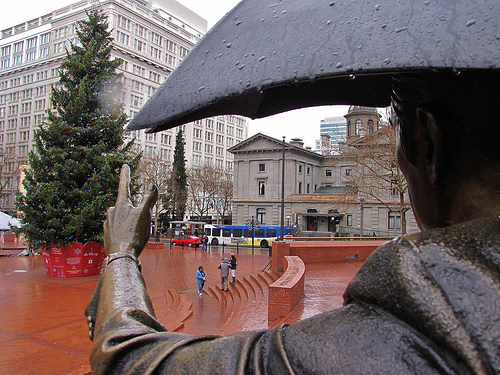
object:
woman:
[195, 265, 206, 297]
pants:
[197, 283, 205, 293]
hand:
[100, 162, 159, 254]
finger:
[115, 159, 132, 198]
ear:
[414, 103, 441, 186]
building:
[0, 0, 252, 236]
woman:
[226, 250, 238, 285]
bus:
[200, 224, 296, 248]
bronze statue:
[85, 0, 500, 374]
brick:
[0, 238, 393, 374]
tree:
[7, 0, 145, 253]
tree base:
[40, 239, 106, 278]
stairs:
[256, 270, 272, 289]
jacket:
[193, 270, 206, 286]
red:
[80, 257, 85, 269]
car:
[167, 234, 202, 249]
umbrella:
[128, 0, 498, 137]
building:
[225, 103, 422, 241]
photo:
[0, 0, 499, 375]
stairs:
[262, 268, 281, 282]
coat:
[230, 256, 237, 270]